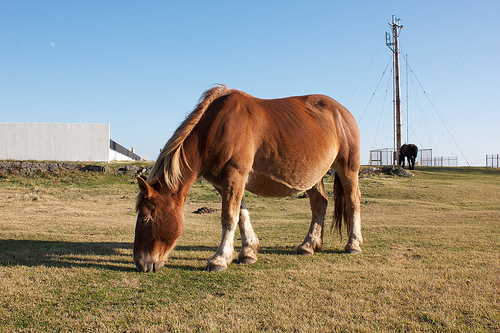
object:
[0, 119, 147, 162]
factory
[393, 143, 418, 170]
cow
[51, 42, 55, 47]
moon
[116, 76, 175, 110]
sky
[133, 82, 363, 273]
mule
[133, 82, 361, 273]
horse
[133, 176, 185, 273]
head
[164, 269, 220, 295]
grass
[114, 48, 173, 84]
sky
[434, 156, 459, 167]
fence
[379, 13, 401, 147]
pole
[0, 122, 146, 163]
building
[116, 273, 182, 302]
grass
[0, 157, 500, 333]
pasture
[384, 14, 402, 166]
tower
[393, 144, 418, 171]
horse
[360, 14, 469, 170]
antenna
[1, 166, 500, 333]
field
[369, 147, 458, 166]
fencing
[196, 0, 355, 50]
sky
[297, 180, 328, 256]
leg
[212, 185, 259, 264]
leg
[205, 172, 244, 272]
leg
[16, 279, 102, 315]
grass